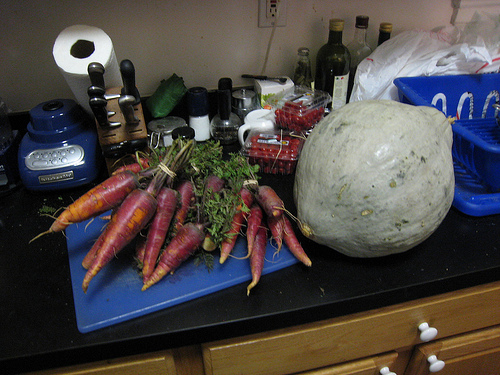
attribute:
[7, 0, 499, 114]
wall — white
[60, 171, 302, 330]
cutting board — blue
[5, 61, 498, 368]
counter — black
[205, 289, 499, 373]
drawers — brown, wooden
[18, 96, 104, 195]
blender — blue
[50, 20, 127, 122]
towel — white, paper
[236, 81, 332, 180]
tomatoes — red, cherry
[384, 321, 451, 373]
knobs — white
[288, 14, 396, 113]
bottles — glass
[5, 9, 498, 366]
scene — kitchen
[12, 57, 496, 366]
countertop — black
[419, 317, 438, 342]
drawer pull — white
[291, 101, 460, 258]
gourd — large, grey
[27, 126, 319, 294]
carrots — purple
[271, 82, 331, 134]
pack — tomatoes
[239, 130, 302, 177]
pack — tomatoes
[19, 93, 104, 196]
bottom — blender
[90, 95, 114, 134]
knife — here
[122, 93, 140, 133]
knife — here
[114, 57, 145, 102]
knife — here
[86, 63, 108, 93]
knife — here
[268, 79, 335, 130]
container — tomatoes, clear, plastic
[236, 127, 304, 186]
container — tomatoes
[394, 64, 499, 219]
dish rack — plastic, blue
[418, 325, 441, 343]
knob — white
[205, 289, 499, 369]
drawer — wooden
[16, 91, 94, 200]
base — blender's, blue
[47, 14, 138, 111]
roll — paper, towels, white, toilet paper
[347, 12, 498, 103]
bags — plastic, grocery, white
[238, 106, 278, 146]
mug — white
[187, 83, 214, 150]
shaker — salt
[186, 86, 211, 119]
top — black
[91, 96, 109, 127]
handle — black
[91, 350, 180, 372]
door — wooden, brown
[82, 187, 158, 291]
carrot — orange, purple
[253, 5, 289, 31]
socket — electrical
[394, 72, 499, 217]
dish drainer — here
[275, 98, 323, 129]
tomatoes — cherry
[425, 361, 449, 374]
handle — white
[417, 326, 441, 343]
handle — white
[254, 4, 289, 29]
outlet — electrical